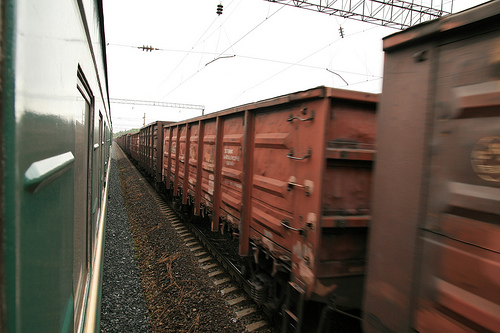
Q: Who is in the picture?
A: Nobody.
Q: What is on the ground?
A: Rocks.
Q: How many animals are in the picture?
A: None.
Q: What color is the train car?
A: Red.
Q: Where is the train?
A: On the track.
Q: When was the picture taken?
A: Daytime.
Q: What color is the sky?
A: Gray.